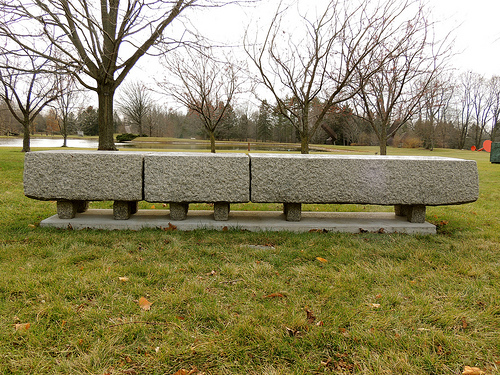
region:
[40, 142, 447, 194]
the structure is stone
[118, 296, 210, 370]
the grass is short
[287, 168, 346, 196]
the structure is grey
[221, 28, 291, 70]
branches in the sky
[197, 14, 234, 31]
the sky is bright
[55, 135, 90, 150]
the body of water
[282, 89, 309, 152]
trunk of the tree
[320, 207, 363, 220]
shadow on the ground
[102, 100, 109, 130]
the trunk is brown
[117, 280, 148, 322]
leaves on the grass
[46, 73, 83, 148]
The tree is barren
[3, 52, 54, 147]
The tree is barren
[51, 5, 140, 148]
The tree is barren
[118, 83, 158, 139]
The tree is barren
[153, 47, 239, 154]
The tree is barren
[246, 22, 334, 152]
The tree is barren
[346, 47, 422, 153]
The tree is barren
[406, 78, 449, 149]
The tree is barren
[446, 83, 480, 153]
The tree is barren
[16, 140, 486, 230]
Large stone display on the ground.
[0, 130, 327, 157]
Water in the background.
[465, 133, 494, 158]
Red objects in the background.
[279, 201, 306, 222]
Stone leg on the block.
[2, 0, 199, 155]
Tree by the cement blocks.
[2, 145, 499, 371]
Green grass covering the ground.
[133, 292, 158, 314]
brown leaf on the ground.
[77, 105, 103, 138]
Green tree in the background.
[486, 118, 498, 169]
Green object in the background.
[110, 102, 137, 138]
House in the bacground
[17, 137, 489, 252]
stone bench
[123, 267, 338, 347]
brown leaves on grass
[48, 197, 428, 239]
stone bench legs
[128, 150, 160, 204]
line in seat of stone bench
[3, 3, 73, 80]
bare brown tree branches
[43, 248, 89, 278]
patch of green grass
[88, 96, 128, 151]
brown tree trunk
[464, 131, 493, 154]
orange object in grass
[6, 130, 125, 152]
paved surface on ground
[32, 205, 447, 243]
stone slab bench foundation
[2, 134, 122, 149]
Water by the trees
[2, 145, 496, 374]
A grassy field beneath the stone design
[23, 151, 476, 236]
A stone design in the field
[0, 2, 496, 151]
Trees near the water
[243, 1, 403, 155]
The tree is bare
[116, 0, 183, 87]
A branch on the tree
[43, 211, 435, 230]
A concrete base on the grass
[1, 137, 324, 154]
Water behind the concrete design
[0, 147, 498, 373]
Green grass in the field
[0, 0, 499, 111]
The sky above the grassy field